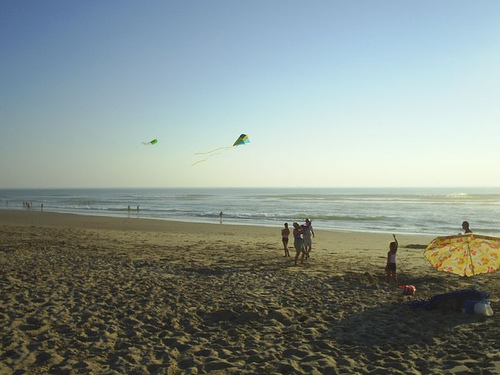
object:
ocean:
[0, 189, 500, 237]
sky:
[7, 3, 500, 192]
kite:
[191, 133, 250, 165]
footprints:
[116, 274, 227, 373]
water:
[289, 188, 499, 218]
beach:
[1, 209, 499, 372]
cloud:
[119, 74, 210, 117]